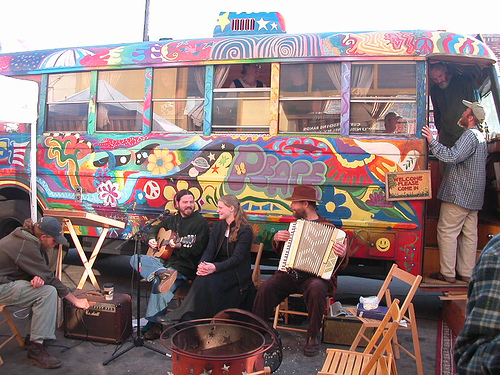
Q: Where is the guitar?
A: In the man's lap.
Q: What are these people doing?
A: Playing music.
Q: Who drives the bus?
A: Bus driver.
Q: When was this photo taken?
A: Daytime.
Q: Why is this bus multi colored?
A: It's a hippie bus.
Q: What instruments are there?
A: Guitar and accordian.